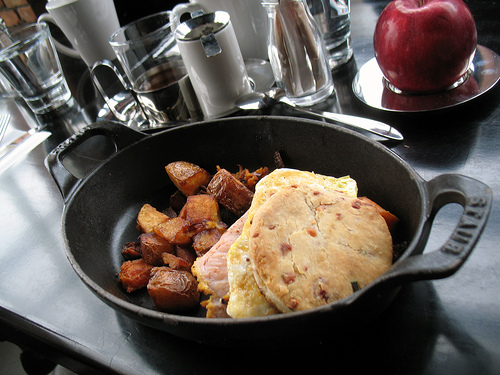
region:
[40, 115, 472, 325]
a pan full of food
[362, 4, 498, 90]
a ripe red apple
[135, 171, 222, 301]
a small pile of breakfast potatoes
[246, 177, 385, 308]
a large pancake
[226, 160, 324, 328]
a couple of eggs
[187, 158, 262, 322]
the edge of a slice of ham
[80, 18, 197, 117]
a glass of water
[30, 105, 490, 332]
a cast iron pan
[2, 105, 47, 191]
a napkin holding silverware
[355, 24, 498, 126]
a small saucer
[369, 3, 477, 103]
the apple is red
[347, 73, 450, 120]
the plate is silver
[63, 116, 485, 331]
the pan is mettalic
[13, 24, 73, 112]
the glass has water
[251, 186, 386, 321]
the pancakes are brown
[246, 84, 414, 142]
the spoon is mettalic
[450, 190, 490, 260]
the letters are mettalic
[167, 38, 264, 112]
the object is white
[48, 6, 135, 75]
the cup is white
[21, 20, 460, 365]
the table is full of utensils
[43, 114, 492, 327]
An iron skillet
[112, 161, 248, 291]
some hash browns in the skillet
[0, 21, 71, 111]
A clear drinking glass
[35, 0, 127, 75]
A white coffee mug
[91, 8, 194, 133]
A clear cup on a plate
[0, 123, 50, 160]
A silver knife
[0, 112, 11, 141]
A silver fork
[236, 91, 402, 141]
A silver spoon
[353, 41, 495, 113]
A silver plate on a table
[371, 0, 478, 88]
an apple on a plate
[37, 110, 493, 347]
a skillet of breakfast food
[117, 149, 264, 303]
brown crispy cooked potatoes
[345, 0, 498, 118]
a red apple on a silver plate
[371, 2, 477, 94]
red shiny apple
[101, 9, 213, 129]
glass of water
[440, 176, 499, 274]
skillet manufacturer name on handle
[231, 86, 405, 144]
silverware on a table behind a skillet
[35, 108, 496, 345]
block iron two handled skillet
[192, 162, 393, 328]
a breakfast sandwich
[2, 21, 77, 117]
a full glass of water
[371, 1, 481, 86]
this is an apple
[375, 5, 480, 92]
the apple is big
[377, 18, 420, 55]
the apple is red in color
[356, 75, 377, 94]
this is a saucer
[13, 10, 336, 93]
these are several glasses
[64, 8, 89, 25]
the cup is white in color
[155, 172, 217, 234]
this is some beef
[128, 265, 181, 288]
the beef is brown in color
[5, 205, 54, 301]
this is a table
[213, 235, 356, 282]
this is a bun